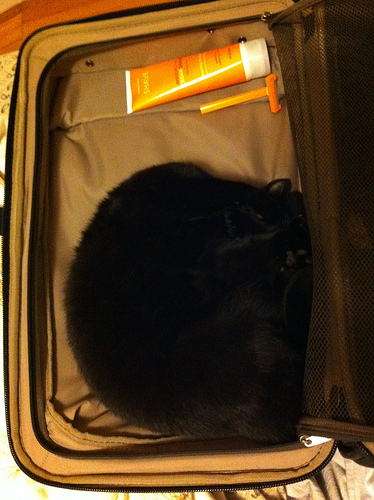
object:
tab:
[299, 434, 335, 449]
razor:
[197, 72, 281, 114]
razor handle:
[199, 88, 267, 115]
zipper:
[8, 444, 339, 496]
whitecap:
[236, 35, 273, 81]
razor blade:
[265, 72, 283, 113]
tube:
[125, 35, 272, 114]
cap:
[236, 36, 271, 80]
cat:
[64, 161, 317, 450]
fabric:
[0, 440, 137, 500]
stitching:
[44, 381, 118, 451]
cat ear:
[263, 177, 293, 198]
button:
[84, 58, 96, 70]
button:
[206, 28, 216, 36]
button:
[236, 35, 248, 44]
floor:
[0, 0, 177, 55]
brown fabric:
[327, 462, 374, 500]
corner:
[27, 352, 129, 463]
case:
[0, 0, 374, 500]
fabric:
[266, 0, 373, 445]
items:
[124, 37, 281, 112]